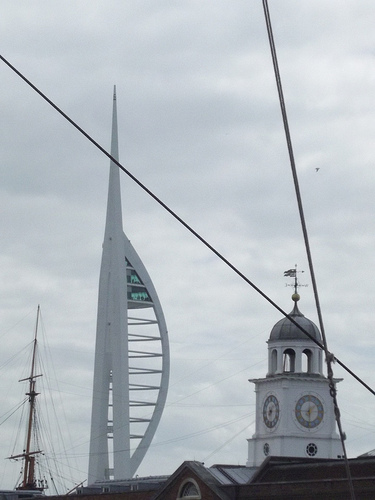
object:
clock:
[291, 390, 327, 430]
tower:
[243, 255, 349, 465]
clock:
[257, 390, 283, 433]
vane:
[281, 260, 310, 298]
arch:
[279, 347, 298, 374]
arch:
[299, 345, 312, 375]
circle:
[302, 439, 319, 458]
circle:
[259, 440, 271, 458]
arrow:
[283, 279, 310, 291]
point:
[291, 261, 299, 272]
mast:
[9, 300, 48, 487]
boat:
[0, 451, 47, 499]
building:
[115, 454, 374, 500]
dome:
[262, 311, 322, 351]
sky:
[1, 2, 373, 497]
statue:
[83, 78, 172, 489]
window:
[174, 478, 201, 499]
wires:
[1, 54, 374, 393]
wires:
[257, 3, 360, 500]